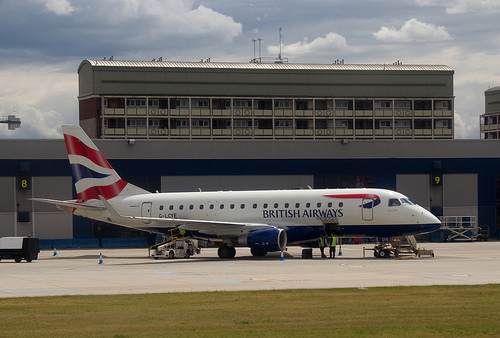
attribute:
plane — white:
[33, 115, 455, 282]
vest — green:
[316, 236, 337, 248]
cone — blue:
[93, 243, 108, 271]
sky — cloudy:
[28, 4, 344, 56]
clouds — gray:
[18, 11, 165, 56]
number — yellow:
[13, 176, 33, 197]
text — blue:
[253, 205, 352, 228]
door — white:
[133, 196, 160, 231]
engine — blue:
[229, 219, 291, 268]